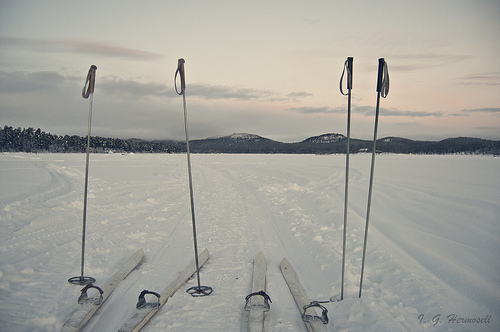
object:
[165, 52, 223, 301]
pole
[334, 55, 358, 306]
pole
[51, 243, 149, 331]
ski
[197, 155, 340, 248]
snow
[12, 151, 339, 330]
tracks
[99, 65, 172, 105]
cloud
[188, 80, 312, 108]
cloud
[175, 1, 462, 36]
part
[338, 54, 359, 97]
hooker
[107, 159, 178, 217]
part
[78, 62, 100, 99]
belt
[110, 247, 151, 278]
tip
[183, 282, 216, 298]
bottom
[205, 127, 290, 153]
part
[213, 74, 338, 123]
part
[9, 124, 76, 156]
part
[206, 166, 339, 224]
surface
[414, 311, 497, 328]
name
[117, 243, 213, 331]
ski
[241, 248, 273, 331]
ski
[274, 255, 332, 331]
ski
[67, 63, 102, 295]
pole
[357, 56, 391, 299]
poles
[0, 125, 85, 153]
trees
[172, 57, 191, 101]
holder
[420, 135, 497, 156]
hills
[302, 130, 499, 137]
horizon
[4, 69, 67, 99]
clouds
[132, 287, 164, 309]
binder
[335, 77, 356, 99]
part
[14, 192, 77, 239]
part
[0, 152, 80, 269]
line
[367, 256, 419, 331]
part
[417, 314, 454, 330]
part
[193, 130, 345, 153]
mountain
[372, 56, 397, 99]
hooker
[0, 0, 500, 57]
sky